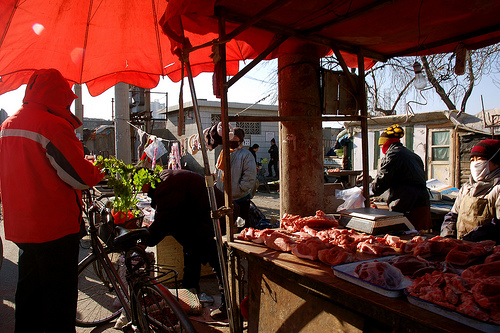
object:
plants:
[91, 151, 165, 227]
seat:
[104, 222, 155, 249]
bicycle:
[78, 185, 195, 333]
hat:
[376, 123, 406, 145]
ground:
[448, 140, 476, 165]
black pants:
[13, 237, 80, 332]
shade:
[280, 283, 357, 330]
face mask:
[470, 159, 490, 183]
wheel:
[132, 282, 200, 333]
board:
[232, 257, 375, 333]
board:
[213, 233, 500, 333]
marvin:
[377, 123, 404, 148]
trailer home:
[344, 110, 479, 198]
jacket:
[0, 66, 100, 244]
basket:
[137, 265, 183, 292]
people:
[215, 127, 500, 244]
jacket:
[215, 148, 257, 199]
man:
[140, 168, 234, 321]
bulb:
[30, 22, 46, 36]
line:
[127, 93, 276, 143]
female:
[442, 137, 500, 243]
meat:
[436, 241, 499, 325]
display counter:
[228, 212, 500, 333]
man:
[366, 122, 430, 234]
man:
[0, 67, 107, 333]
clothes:
[135, 123, 235, 171]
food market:
[0, 0, 500, 333]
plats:
[73, 212, 198, 333]